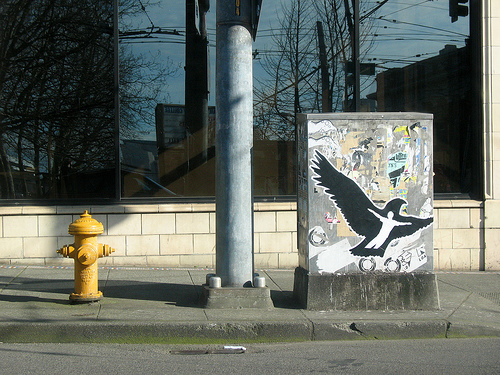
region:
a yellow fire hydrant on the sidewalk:
[56, 208, 113, 303]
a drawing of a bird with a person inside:
[309, 147, 437, 257]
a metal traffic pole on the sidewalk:
[200, 0, 275, 307]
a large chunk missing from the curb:
[325, 320, 367, 337]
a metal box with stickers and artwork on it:
[295, 110, 445, 310]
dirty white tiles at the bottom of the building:
[0, 196, 499, 272]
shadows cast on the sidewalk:
[1, 271, 296, 310]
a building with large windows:
[1, 1, 498, 271]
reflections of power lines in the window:
[117, 0, 472, 61]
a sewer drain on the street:
[168, 346, 248, 357]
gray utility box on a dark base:
[298, 110, 438, 274]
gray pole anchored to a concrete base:
[216, 2, 258, 285]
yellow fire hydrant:
[57, 209, 117, 299]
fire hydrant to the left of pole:
[56, 210, 121, 302]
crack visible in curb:
[328, 322, 364, 335]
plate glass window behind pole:
[1, 1, 484, 198]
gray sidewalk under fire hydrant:
[1, 264, 499, 324]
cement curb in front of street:
[1, 318, 499, 343]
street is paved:
[1, 340, 498, 373]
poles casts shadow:
[3, 274, 212, 307]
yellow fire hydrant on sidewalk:
[50, 208, 126, 308]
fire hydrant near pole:
[50, 206, 122, 308]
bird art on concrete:
[305, 145, 435, 261]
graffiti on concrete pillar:
[307, 120, 432, 277]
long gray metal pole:
[207, 2, 266, 292]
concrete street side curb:
[3, 318, 498, 349]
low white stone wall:
[0, 193, 499, 274]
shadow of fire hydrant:
[0, 287, 90, 307]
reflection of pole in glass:
[177, 0, 213, 195]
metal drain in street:
[168, 343, 249, 357]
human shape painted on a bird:
[364, 198, 416, 262]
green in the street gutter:
[141, 330, 268, 359]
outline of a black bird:
[309, 140, 433, 268]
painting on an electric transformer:
[306, 114, 431, 275]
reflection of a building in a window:
[127, 57, 200, 177]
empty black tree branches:
[21, 66, 92, 158]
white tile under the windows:
[124, 211, 209, 264]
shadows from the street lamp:
[114, 275, 199, 319]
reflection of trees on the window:
[267, 46, 334, 107]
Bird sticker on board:
[315, 148, 434, 270]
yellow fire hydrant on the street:
[48, 206, 127, 311]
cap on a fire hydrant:
[71, 243, 99, 273]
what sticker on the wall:
[363, 205, 411, 260]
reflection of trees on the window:
[6, 23, 106, 203]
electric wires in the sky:
[282, 10, 462, 72]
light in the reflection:
[445, 0, 466, 24]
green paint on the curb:
[111, 333, 392, 344]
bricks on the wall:
[132, 203, 214, 268]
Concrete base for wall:
[307, 270, 442, 308]